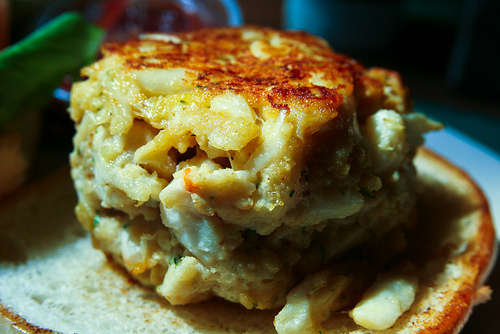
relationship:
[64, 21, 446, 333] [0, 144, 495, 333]
crab cake on bread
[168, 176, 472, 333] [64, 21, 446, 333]
shadow of crab cake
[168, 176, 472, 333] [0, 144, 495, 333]
shadow on bread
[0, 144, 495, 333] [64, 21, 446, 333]
bread under crab cake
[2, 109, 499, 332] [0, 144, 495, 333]
plate under bread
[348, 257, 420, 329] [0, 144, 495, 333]
onion on bread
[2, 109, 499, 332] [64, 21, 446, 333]
plate has crab cake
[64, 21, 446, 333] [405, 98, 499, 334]
crab cake on table